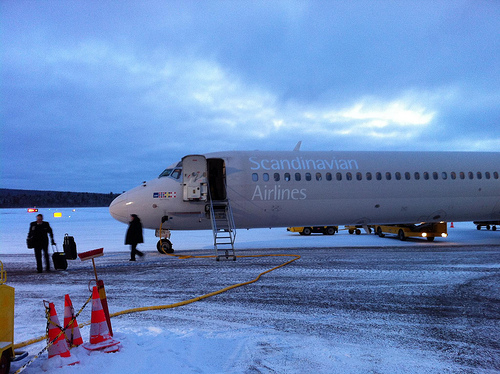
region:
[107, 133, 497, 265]
A large aircraft on a runway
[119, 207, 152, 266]
A woman walking by the airplane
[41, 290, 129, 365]
Several orange and white traffic cones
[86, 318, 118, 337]
A small white stripe on the traffic cone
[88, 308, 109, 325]
An orange stripe on the traffic cone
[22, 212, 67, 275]
A man holding a suitcase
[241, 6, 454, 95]
Thick grey clouds hanging in the sky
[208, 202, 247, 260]
A ladder by the exit of the plane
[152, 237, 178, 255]
A small black wheel under the plane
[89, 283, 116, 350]
an orange and white striped cone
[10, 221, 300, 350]
a yellow cord running out to an airplane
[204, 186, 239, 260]
stairs going up to an airplane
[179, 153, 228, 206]
the open door of an airplane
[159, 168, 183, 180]
the front windows of an airplane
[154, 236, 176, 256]
the nose wheel of an airplane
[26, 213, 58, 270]
a man pulling a suitcase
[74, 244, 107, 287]
a small brush in a cone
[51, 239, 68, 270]
a suitcase pulled by a man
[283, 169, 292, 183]
a window on an airplane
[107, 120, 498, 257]
A Scandinavian Airlines jet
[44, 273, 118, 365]
The safety cones on the left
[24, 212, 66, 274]
The person carrying a suitcase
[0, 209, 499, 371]
A snow covered airport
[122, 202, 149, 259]
The walking woman next to the plane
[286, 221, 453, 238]
The yellow trucks behind the plane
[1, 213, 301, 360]
The long yellow rope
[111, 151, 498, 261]
A white long jet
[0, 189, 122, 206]
The dark background vegetation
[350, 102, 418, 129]
white clouds in the sky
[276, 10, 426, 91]
dark clouds in the sky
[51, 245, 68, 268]
a travelling bag being pulled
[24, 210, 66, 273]
a man pulling a travelling bag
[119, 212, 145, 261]
a person walking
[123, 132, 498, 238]
a plane on the ground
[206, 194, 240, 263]
a ladder into the plane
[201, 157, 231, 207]
the door of a plane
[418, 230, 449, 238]
the lights of a truck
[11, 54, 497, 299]
a commercial jet parked on a runway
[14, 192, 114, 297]
a man walking away from a jet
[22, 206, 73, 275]
a man carrying a bag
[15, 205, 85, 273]
a man pulling a bag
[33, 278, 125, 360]
yellow and orange hazard cones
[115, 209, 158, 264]
a person walking in front of a jet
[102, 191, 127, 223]
the nosecone of a jet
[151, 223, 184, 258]
the nose gear of a jet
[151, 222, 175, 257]
the landing gear of a jet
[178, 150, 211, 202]
an opened passenger door on a jet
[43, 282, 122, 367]
stack of traffic warning cones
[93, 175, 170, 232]
nose on the plane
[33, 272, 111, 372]
a set of cones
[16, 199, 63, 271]
man near the plane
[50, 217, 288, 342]
hose on the ground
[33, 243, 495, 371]
snow on the ground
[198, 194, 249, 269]
a set of stairs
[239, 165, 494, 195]
a row of windwos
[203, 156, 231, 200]
doorway on the plane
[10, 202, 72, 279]
man holding a suitcase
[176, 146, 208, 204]
door of the plane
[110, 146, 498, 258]
the front of an airplane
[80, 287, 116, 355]
a large orange and white cone